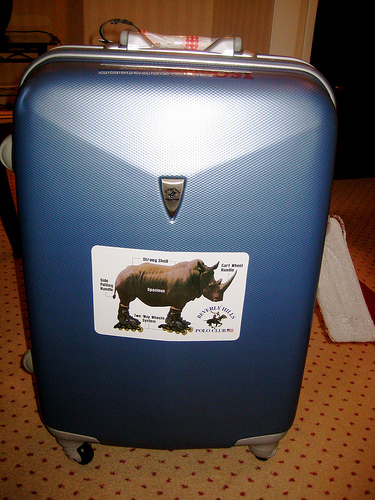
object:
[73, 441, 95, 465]
wheel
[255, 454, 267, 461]
wheel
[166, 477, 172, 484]
dots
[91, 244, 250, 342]
sticker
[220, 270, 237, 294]
horn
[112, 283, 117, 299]
tail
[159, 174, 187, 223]
logo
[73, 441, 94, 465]
tires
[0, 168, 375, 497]
floor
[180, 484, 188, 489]
spots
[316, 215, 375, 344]
cloth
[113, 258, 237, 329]
animal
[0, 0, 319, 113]
wall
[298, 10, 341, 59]
wood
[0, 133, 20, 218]
thing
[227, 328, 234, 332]
flag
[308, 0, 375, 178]
door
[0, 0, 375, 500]
room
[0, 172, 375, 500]
carpet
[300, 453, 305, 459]
dots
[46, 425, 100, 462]
casing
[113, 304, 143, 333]
roller skates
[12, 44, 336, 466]
bag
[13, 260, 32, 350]
shadow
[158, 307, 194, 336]
roller blades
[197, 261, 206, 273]
ear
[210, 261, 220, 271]
ear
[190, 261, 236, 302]
head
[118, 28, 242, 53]
handle